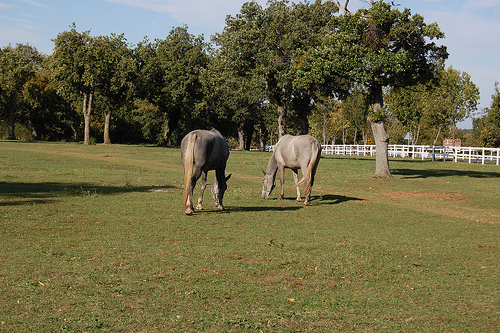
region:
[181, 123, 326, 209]
the horses are gray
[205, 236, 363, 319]
the grass is green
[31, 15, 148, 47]
the sky is blue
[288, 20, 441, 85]
the trees are green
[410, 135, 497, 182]
the fence is white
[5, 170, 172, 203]
the shadow is dark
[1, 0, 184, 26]
the sky is clear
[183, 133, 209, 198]
the horse's tale is blonde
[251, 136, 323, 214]
the horse is eating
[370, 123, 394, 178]
the bark is gray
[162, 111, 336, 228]
Horses are grey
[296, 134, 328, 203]
Horse tail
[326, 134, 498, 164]
White fence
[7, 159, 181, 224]
Shadow cast in the ground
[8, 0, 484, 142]
Big green trees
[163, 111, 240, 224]
Horse is eating green grass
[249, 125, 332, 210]
Horse is eating green grass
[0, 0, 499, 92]
Sky is blue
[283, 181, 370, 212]
Shadow of horse cast on the ground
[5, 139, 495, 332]
Horse corral is cover with green grass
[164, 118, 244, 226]
a brown horse grazing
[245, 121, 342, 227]
a grey horse grazing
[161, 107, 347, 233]
two horses grazing side by side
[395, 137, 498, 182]
a white picket fence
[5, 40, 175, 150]
a group of trees with greet leaves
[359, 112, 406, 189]
a tree trunk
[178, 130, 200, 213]
a horses tail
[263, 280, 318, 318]
a leave in the grass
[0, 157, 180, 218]
a large shadow on the ground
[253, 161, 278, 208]
a horse with a blue bridal on its face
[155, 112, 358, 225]
two brown horses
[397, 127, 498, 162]
white wooden fence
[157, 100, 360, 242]
two brown horses grazing on grass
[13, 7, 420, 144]
tall green leafy trees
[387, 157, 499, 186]
shadow cast by tree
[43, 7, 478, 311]
horse ranch surrounded by white fence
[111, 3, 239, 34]
blue sky with wispy white clouds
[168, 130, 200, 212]
long light brown tail of horse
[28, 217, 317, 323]
green grass for horses to graze on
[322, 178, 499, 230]
pathway made through grassy area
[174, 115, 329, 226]
Two gray horses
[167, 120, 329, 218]
A couple of gray horses grazing in a field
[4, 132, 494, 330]
A green field with brown leaves scattered throughout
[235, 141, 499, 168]
A white picket fence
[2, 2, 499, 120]
A blue sky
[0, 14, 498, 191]
A row of trees with green leaves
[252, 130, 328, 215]
A gray horse with its head down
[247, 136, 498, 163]
A white fence in the background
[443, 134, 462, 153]
A building in the distance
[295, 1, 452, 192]
A tree next to two horses